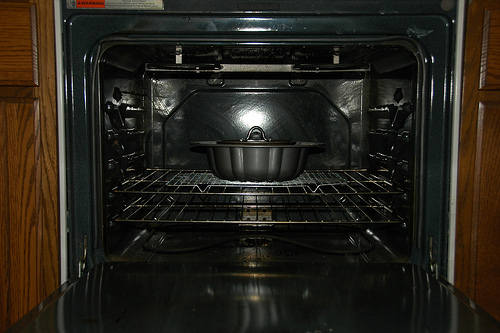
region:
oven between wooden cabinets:
[12, 2, 492, 312]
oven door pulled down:
[11, 230, 483, 325]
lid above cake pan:
[190, 117, 316, 178]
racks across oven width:
[105, 155, 405, 250]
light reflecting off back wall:
[227, 96, 272, 132]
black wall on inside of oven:
[72, 10, 447, 295]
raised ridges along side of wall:
[100, 80, 145, 231]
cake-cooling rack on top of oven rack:
[161, 156, 341, 191]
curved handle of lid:
[231, 121, 271, 141]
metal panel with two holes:
[235, 205, 275, 225]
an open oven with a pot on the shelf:
[71, 13, 448, 298]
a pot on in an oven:
[194, 126, 326, 188]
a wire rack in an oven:
[116, 161, 409, 199]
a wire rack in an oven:
[106, 194, 412, 230]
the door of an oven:
[42, 262, 487, 327]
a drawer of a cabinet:
[1, 0, 42, 91]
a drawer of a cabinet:
[474, 5, 499, 92]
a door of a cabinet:
[1, 91, 45, 317]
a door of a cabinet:
[465, 97, 496, 312]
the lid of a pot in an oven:
[208, 123, 313, 148]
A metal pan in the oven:
[198, 125, 320, 178]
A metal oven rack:
[114, 165, 393, 197]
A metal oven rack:
[107, 193, 402, 225]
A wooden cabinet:
[3, 1, 57, 309]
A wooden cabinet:
[453, 2, 497, 317]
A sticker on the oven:
[73, 0, 163, 10]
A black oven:
[61, 2, 455, 280]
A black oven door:
[0, 265, 497, 330]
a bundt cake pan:
[198, 137, 316, 182]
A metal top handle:
[242, 124, 269, 141]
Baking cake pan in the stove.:
[170, 81, 330, 191]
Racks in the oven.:
[105, 199, 401, 231]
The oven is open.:
[71, 108, 466, 280]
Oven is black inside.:
[86, 64, 388, 215]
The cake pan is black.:
[192, 108, 334, 178]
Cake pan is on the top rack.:
[171, 109, 333, 206]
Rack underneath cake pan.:
[162, 170, 362, 197]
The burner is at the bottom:
[136, 232, 375, 265]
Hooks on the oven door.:
[417, 240, 446, 280]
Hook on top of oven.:
[196, 48, 294, 67]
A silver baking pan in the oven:
[193, 138, 320, 183]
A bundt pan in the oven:
[192, 138, 319, 181]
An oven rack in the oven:
[113, 165, 407, 197]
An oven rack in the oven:
[113, 192, 406, 229]